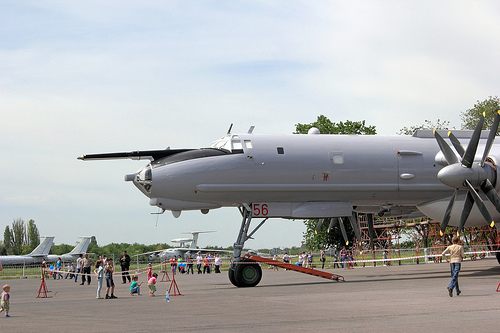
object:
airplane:
[77, 111, 499, 289]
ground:
[1, 248, 497, 333]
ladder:
[244, 251, 347, 283]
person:
[441, 236, 466, 298]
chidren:
[144, 273, 160, 297]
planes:
[0, 235, 95, 266]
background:
[0, 2, 500, 274]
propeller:
[433, 121, 498, 229]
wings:
[428, 108, 500, 237]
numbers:
[251, 203, 269, 217]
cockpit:
[194, 129, 256, 155]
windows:
[228, 140, 248, 155]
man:
[74, 254, 84, 282]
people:
[93, 261, 105, 299]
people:
[80, 253, 92, 286]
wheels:
[226, 258, 261, 289]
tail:
[174, 230, 211, 247]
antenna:
[354, 119, 372, 134]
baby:
[0, 284, 11, 320]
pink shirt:
[147, 276, 156, 283]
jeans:
[450, 264, 462, 293]